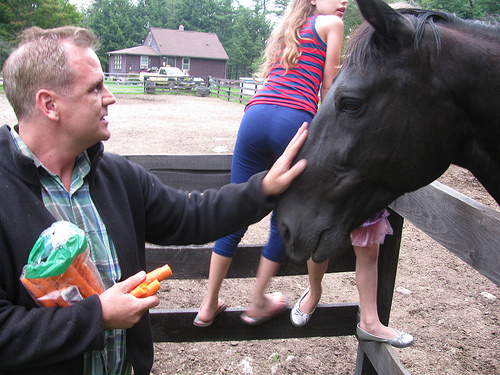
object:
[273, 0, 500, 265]
horse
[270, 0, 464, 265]
head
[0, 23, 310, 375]
man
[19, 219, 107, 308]
bag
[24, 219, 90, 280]
top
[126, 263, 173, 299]
carrots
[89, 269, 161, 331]
hand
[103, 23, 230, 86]
house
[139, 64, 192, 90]
truck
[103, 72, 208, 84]
fence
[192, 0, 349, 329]
girl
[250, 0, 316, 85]
hair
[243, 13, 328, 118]
top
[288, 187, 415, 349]
girl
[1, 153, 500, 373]
fence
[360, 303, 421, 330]
shoes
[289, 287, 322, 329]
shoes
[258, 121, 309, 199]
hand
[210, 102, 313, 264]
pants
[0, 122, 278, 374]
jacket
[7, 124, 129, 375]
shirt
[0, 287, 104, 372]
arm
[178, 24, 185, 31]
chimney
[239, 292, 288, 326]
flip flops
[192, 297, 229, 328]
flip flops